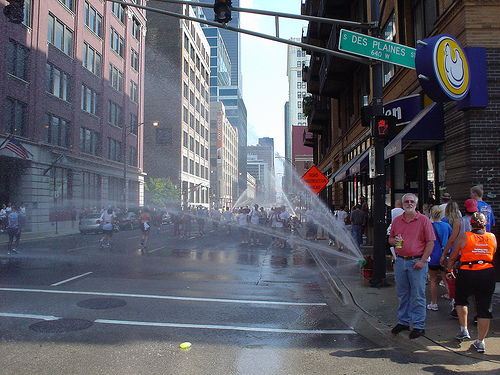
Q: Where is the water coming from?
A: Fire hydrant.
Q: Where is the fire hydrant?
A: On the street.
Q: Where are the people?
A: On the sidewalk.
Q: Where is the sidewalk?
A: Beside the street.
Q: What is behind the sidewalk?
A: Buildings.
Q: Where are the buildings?
A: Behind the people.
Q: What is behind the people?
A: Buildings.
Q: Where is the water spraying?
A: On the street.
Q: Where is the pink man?
A: On the sidewalk.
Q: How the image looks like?
A: Busy.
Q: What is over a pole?
A: Sign.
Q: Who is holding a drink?
A: The man in the pink shirt.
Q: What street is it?
A: Des Plaines.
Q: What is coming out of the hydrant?
A: Water.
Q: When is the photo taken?
A: Daytime.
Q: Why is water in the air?
A: It is coming from the hydrant.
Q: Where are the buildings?
A: Adjacent to the road.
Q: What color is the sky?
A: Blue.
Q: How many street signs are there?
A: One.